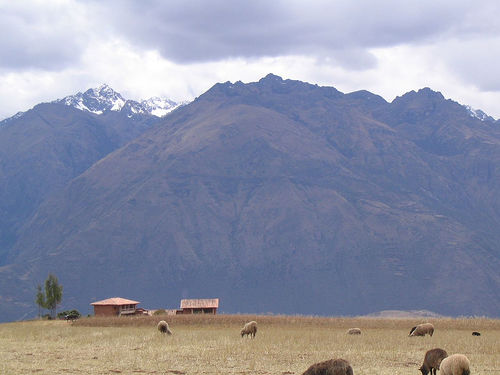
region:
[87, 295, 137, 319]
house at edge of the field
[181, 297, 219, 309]
Barn at edge of the field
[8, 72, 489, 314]
mountain range behind house and barn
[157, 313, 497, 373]
sheep in the field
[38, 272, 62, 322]
tall tree behind house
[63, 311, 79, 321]
dark colored animal close to house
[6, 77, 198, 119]
snow on top on mountain on left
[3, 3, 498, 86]
clouds over mountain tops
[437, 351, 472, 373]
white sheep in bottom left hand corner of photo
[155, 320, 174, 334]
light sheep on left of field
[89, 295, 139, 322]
small orange house on plane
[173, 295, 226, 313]
orange roof to small house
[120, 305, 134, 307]
windows on top of house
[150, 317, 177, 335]
white sheep in field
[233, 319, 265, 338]
white sheep in field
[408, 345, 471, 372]
two sheep grazing together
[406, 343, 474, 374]
white and dark brown sheep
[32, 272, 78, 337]
small tree standing in grass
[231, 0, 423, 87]
white puffy clouds in sky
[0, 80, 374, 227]
large mountain range with snow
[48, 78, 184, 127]
show covered mountain peaks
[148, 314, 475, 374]
sheep grazing in field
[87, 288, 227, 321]
two buildings in field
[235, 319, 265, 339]
one sheep grazing in field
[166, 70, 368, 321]
small building in front of mountain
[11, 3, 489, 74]
sky with many clouds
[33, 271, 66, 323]
one tree in field of brown grass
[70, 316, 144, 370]
brown grass field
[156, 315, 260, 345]
two sheep grazing in field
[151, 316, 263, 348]
two sheep eating brown grass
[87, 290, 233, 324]
Two small houses in front of a mountain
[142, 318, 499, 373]
A field of grazing sheep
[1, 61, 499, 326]
Several big mountains some with snow caps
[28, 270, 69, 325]
One lonely tree next to a house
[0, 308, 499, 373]
A field of brown grass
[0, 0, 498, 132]
Dark thick cloud filled sky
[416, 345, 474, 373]
One light haired sheep next to a dark haired sheep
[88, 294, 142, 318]
One story wooden house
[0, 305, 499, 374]
Dry brown grass land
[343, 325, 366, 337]
Sheep lying in a field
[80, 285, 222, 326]
two small buildings in a field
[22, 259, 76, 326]
two trees in a field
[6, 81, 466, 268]
tall mountains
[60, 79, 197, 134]
a mountain top covered with snow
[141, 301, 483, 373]
sheep grazing in a field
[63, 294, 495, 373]
sheep eating grass in a field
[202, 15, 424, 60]
dark clouds in the sky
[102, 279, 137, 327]
red building with a red roof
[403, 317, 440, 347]
a sheep grazing in a field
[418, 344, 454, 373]
a brown sheep eating grass